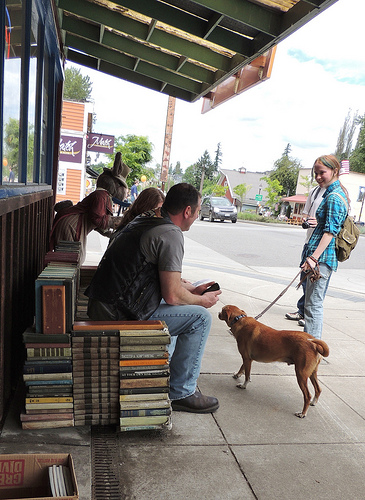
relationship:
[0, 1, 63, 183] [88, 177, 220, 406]
window behind man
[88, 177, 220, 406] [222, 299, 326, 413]
man beside dog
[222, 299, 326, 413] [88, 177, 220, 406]
dog beside man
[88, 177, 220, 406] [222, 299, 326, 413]
man near dog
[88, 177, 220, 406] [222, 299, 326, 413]
man close to dog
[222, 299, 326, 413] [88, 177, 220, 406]
dog near man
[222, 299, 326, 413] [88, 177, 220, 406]
dog close to man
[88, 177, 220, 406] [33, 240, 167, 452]
man on books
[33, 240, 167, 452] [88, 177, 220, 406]
books under man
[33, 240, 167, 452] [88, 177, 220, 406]
books below man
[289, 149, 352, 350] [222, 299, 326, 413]
girl close to dog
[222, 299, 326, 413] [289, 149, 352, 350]
dog close to girl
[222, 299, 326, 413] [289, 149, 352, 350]
dog beside girl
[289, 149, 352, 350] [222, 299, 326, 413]
girl beside dog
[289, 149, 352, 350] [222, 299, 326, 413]
girl above dog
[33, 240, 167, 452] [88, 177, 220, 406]
books close to man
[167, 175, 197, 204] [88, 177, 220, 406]
hair of man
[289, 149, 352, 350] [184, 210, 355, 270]
girl close to street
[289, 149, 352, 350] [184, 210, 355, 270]
girl beside street